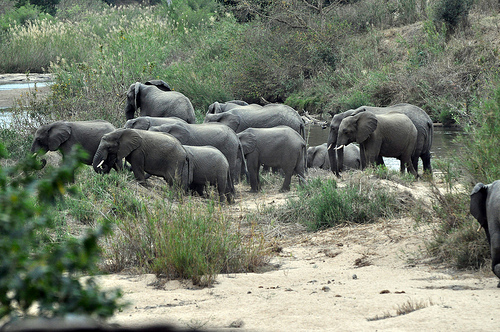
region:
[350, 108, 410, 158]
elephant in the field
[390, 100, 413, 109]
elephant in the field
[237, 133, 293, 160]
elephant in the field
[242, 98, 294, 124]
elephant in the field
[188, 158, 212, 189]
elephant in the field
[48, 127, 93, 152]
elephant in the field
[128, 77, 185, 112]
elephant in hte field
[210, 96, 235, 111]
elephant in the field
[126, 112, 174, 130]
elephant in the field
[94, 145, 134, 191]
this is a tusk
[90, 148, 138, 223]
the tusk is ivory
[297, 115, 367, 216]
this is a trunk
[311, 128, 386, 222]
the trunk is long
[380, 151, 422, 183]
this is a tail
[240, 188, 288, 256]
this is a leg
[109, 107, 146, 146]
this is an ear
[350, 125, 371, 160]
the ear is large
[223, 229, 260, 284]
this is a bush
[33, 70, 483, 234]
elephants in the grass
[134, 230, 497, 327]
the sand beside the elephants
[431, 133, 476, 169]
water beside the elephants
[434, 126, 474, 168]
the water is calm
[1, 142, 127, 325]
bush in the foreground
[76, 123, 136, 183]
head of the elephant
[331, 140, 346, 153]
tusk on the elephant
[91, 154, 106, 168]
tusk on the elephant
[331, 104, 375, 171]
head of the elephant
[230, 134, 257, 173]
tail of the elephant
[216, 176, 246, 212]
leg of an elephant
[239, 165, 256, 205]
leg of an elephant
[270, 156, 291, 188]
leg of an elephant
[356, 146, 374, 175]
leg of an elephant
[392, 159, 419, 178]
leg of an elephant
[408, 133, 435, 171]
leg of an elephant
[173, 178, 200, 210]
leg of an elephant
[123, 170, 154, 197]
leg of an elephant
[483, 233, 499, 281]
leg of an elephant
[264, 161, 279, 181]
leg of an elephant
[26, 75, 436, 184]
a herd of elephants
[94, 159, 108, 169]
the elephant's white tusk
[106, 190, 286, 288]
a patch of tall grass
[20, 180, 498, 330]
a sandy area of the ground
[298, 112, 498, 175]
a watering hole behind the elephants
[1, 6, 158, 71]
tall grass growing near the water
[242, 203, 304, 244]
dried sticks and plants on the ground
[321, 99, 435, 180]
two elephants walking closely together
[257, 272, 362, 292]
pebbles on the ground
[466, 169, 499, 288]
an elephant straggling behind the herd